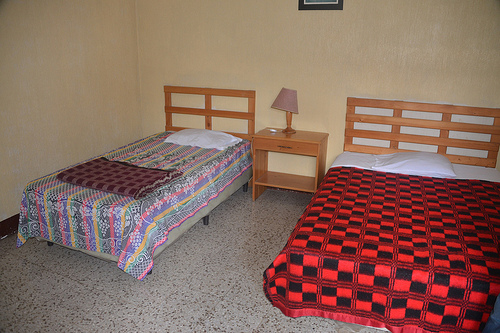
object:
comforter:
[370, 151, 456, 179]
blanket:
[262, 167, 500, 333]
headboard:
[341, 96, 498, 168]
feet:
[203, 215, 209, 225]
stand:
[252, 127, 329, 202]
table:
[269, 129, 278, 134]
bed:
[282, 97, 500, 333]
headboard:
[163, 85, 256, 142]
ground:
[180, 231, 250, 274]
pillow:
[371, 150, 458, 179]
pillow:
[164, 129, 243, 151]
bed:
[22, 83, 254, 275]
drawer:
[253, 137, 318, 155]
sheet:
[15, 131, 254, 281]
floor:
[2, 281, 261, 333]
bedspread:
[55, 156, 183, 200]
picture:
[297, 0, 343, 10]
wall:
[136, 0, 499, 174]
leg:
[243, 181, 249, 193]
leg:
[241, 181, 250, 193]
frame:
[298, 0, 343, 10]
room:
[0, 0, 500, 333]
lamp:
[270, 86, 299, 134]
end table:
[248, 127, 329, 201]